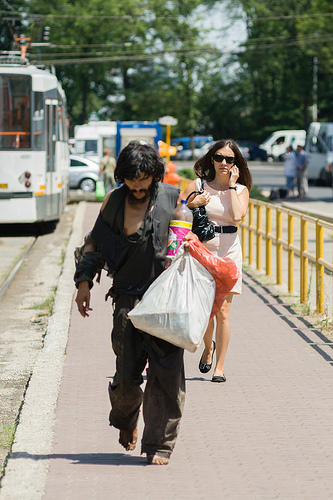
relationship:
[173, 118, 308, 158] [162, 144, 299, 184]
cars are on street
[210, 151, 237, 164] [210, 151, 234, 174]
sunglasses on woman's face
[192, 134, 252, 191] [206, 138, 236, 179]
hair on woman's head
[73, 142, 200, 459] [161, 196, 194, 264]
man holding bottle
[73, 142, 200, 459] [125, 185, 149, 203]
man has a beard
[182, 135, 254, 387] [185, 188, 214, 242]
woman carrying her purse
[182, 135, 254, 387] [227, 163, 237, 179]
woman talking on cell phone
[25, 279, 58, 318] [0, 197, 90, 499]
weeds are next to curb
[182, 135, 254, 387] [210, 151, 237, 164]
woman wearing sunglasses